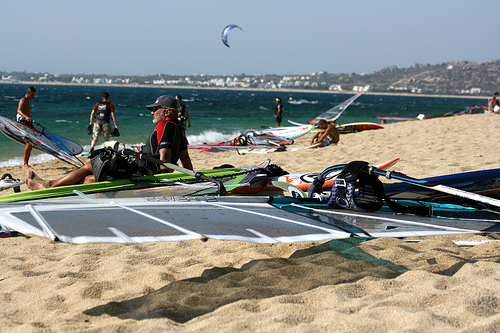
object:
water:
[0, 81, 492, 165]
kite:
[220, 25, 243, 49]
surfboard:
[0, 196, 496, 242]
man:
[16, 86, 42, 166]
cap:
[146, 94, 180, 111]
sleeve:
[156, 120, 176, 150]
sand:
[0, 111, 499, 333]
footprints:
[20, 263, 52, 278]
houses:
[467, 87, 482, 96]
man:
[88, 92, 120, 152]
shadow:
[82, 238, 499, 323]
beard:
[152, 108, 167, 123]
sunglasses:
[151, 105, 159, 112]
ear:
[164, 108, 173, 117]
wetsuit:
[137, 120, 190, 173]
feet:
[25, 173, 50, 190]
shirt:
[91, 101, 116, 121]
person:
[273, 96, 283, 128]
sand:
[0, 78, 499, 100]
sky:
[0, 0, 499, 77]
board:
[0, 117, 85, 170]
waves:
[0, 129, 262, 166]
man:
[309, 118, 340, 146]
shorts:
[91, 121, 113, 139]